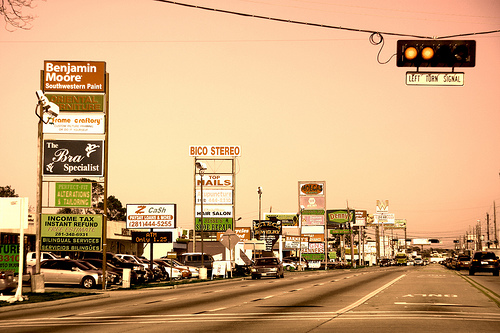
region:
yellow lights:
[393, 39, 434, 67]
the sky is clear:
[175, 68, 242, 110]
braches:
[0, 3, 28, 34]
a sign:
[406, 70, 461, 85]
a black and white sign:
[402, 73, 465, 86]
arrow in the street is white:
[388, 294, 462, 312]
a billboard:
[299, 178, 327, 227]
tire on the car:
[80, 275, 93, 286]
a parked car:
[43, 256, 92, 286]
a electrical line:
[283, 17, 322, 32]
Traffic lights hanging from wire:
[396, 35, 476, 66]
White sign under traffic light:
[405, 70, 465, 86]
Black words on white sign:
[407, 73, 460, 80]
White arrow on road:
[393, 296, 460, 308]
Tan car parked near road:
[29, 257, 114, 285]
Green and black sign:
[43, 213, 102, 254]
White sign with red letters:
[191, 144, 240, 154]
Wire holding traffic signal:
[164, 0, 499, 35]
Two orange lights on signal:
[400, 45, 437, 62]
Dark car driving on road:
[250, 255, 287, 277]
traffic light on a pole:
[390, 27, 480, 87]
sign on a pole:
[16, 52, 112, 95]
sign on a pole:
[35, 87, 110, 108]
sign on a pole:
[185, 126, 240, 166]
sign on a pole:
[40, 135, 115, 180]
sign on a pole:
[45, 176, 103, 216]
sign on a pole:
[35, 210, 110, 237]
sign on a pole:
[295, 212, 326, 227]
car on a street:
[241, 246, 312, 287]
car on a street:
[447, 241, 499, 274]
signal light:
[385, 36, 476, 83]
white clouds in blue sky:
[154, 66, 175, 87]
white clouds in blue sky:
[244, 85, 276, 109]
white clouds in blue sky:
[312, 151, 334, 165]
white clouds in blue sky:
[325, 112, 387, 160]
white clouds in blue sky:
[368, 178, 422, 220]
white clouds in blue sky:
[387, 131, 457, 193]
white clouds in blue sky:
[220, 52, 275, 93]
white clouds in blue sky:
[162, 61, 216, 92]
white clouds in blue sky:
[135, 38, 190, 106]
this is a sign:
[44, 58, 109, 89]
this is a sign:
[42, 90, 110, 111]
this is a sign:
[40, 116, 112, 149]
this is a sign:
[121, 195, 175, 231]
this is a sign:
[284, 170, 331, 270]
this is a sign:
[319, 191, 359, 260]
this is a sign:
[40, 206, 99, 243]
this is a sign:
[44, 176, 99, 207]